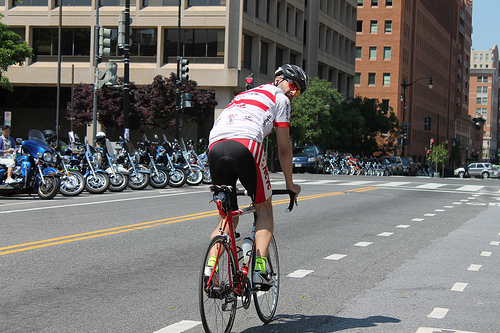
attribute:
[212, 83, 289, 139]
shirt — black, red, white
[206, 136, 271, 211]
shorts — black, red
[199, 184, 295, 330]
bike — red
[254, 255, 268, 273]
sock — yellow, green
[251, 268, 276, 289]
shoe — white, black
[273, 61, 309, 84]
helmet — black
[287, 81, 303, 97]
glasses — red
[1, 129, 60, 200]
motorcycle — blue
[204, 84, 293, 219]
uniform — red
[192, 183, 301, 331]
bicycle — red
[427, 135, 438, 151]
stoplight — red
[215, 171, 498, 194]
crosswalk — striped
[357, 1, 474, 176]
building — brick, tall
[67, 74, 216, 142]
trees — dark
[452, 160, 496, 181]
car — silver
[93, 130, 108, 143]
helmet — white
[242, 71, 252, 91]
light — red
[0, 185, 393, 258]
line — yellow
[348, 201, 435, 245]
line — dotted